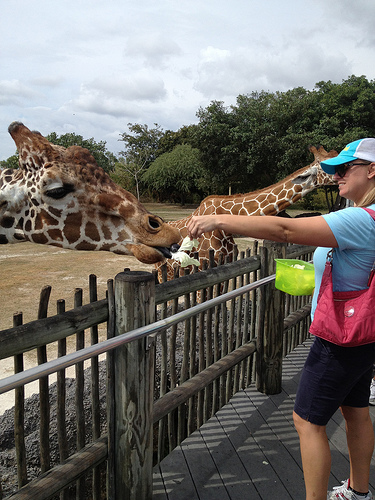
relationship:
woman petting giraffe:
[301, 147, 373, 374] [10, 122, 207, 284]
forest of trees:
[132, 128, 279, 179] [286, 89, 374, 110]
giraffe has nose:
[10, 122, 207, 284] [141, 208, 188, 246]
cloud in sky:
[149, 29, 265, 102] [39, 7, 308, 54]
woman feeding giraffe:
[301, 147, 373, 374] [10, 122, 207, 284]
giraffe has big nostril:
[10, 122, 207, 284] [140, 215, 168, 234]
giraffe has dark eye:
[10, 122, 207, 284] [47, 181, 72, 202]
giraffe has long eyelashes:
[10, 122, 207, 284] [32, 180, 84, 193]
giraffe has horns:
[10, 122, 207, 284] [6, 121, 98, 158]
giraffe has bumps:
[10, 122, 207, 284] [60, 146, 118, 186]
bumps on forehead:
[60, 146, 118, 186] [51, 146, 170, 220]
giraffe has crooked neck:
[182, 174, 342, 258] [194, 180, 294, 233]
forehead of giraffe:
[51, 146, 170, 220] [10, 122, 207, 284]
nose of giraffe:
[141, 208, 188, 246] [10, 122, 207, 284]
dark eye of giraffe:
[47, 181, 72, 202] [10, 122, 207, 284]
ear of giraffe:
[4, 183, 30, 242] [10, 122, 207, 284]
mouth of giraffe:
[129, 227, 182, 269] [10, 122, 207, 284]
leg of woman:
[284, 408, 339, 500] [301, 147, 373, 374]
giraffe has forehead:
[10, 122, 207, 284] [51, 146, 170, 220]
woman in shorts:
[301, 147, 373, 374] [302, 323, 369, 426]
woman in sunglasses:
[301, 147, 373, 374] [331, 153, 360, 185]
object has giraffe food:
[260, 253, 325, 308] [294, 263, 310, 270]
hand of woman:
[175, 205, 220, 239] [301, 147, 373, 374]